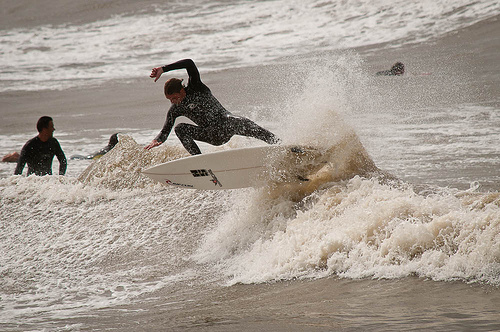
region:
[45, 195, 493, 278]
White water in the ocean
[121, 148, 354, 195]
A white surfboard in the ocean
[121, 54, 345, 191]
A surfer on the surfing board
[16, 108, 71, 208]
A surfer in the water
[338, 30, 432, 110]
A swimmer swimming in the water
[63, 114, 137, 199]
A woman in the ocean water swimming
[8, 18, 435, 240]
A group of swimmers in the ocean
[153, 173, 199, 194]
Black and red writing on the surfboard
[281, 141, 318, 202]
Horns on the end of the board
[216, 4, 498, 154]
A wave getting ready to come up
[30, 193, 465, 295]
A small white water wave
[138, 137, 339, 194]
A white surfboard in the water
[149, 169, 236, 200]
Black and red words on the surfboard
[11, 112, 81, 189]
A man in the ocean watching a swimmer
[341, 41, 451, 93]
A swimmer deeper in the ocean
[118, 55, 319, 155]
A surfer on the surfboard catching a wave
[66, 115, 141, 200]
A woman in the ocean starting to swim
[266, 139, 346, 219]
The tail of the surfboard hits the water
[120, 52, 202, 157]
The surfer holds her arms up for balance on the surfboard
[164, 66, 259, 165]
Surfer falling off the surfboard.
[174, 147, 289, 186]
The surfboard is white.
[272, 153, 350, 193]
The water is brown.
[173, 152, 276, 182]
Line on the surfboard.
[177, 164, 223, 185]
NS on the surfboard.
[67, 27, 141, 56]
White foam on the water.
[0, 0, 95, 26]
The water is grey.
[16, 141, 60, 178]
The wetsuit is black.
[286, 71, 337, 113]
Water in the air.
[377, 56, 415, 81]
Person in the water.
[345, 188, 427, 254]
the water is white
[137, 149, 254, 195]
the surfboard is white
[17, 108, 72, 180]
the man is n the water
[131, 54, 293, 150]
the person is surfing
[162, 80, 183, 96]
the person has hair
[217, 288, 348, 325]
the water is brown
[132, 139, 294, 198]
the board is white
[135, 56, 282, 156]
the man is surfing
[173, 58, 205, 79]
the elbow is bent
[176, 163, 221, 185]
the surfboard has a logo on it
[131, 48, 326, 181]
Man falling off the surfboard.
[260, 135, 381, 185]
The water is brown.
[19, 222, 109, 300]
White foam on the water.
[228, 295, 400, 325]
The water is grey.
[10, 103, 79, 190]
Person in the water.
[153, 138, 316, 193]
The surfboard is white.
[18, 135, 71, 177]
The wetsuit is black.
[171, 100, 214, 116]
Decal on the wetsuit.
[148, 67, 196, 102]
Hair is in a small ponytail.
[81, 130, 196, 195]
Rock next to the person.